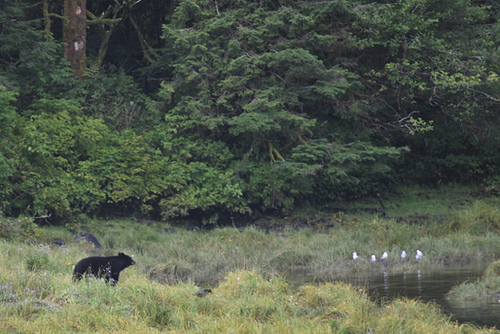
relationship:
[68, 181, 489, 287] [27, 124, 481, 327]
grass litters field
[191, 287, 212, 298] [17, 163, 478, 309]
bird in grass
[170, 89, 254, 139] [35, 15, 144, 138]
leaves on trees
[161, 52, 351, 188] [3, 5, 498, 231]
leaves on trees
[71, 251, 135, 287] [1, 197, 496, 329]
bear stands in grass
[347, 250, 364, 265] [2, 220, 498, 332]
bird stand in grass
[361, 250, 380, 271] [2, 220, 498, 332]
bird stand in grass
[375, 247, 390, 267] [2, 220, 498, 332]
bird stand in grass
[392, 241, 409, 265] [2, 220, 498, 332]
bird stand in grass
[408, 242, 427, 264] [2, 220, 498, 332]
bird stand in grass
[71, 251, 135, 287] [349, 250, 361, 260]
bear watches bird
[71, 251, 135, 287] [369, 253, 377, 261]
bear watches bird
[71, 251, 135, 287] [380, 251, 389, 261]
bear watches bird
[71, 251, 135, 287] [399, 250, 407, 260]
bear watches bird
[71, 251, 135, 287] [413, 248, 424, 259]
bear watches bird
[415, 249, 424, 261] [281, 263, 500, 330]
bird near creek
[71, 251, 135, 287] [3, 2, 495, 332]
bear in forest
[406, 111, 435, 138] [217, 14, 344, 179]
leaves on trees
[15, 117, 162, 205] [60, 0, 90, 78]
leaves on trees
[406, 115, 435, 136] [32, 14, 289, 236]
leaves on tree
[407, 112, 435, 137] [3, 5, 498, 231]
leaves on trees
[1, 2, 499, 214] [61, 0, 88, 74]
leaves on tree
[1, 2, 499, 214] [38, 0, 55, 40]
leaves on tree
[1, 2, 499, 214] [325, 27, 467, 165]
leaves on tree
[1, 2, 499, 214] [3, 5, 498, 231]
leaves on trees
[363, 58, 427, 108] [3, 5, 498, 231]
leaves on trees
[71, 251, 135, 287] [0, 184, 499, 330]
bear in grass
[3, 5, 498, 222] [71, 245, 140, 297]
forest with bear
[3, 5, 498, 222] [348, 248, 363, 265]
forest with bird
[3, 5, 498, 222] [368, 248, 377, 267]
forest with bird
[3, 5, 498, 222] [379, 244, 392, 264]
forest with bird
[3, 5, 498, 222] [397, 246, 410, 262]
forest with bird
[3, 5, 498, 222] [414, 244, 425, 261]
forest with bird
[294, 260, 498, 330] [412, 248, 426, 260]
creek with birds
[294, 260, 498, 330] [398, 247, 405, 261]
creek with birds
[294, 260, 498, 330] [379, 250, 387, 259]
creek with birds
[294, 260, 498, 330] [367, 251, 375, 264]
creek with birds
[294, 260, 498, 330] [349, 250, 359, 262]
creek with birds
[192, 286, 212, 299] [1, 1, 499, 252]
bird in forest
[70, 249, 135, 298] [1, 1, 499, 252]
bear in forest